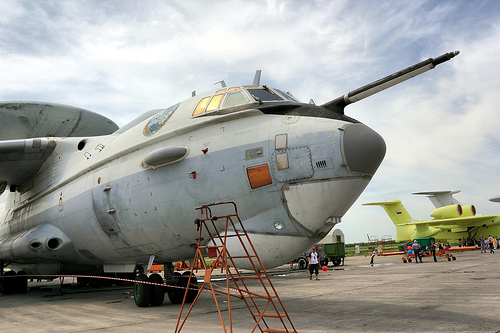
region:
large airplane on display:
[3, 69, 391, 309]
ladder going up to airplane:
[176, 196, 295, 330]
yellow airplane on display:
[379, 198, 491, 230]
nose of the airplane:
[330, 117, 402, 202]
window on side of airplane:
[210, 94, 219, 112]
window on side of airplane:
[198, 102, 205, 120]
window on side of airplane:
[256, 87, 281, 104]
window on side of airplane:
[273, 86, 296, 100]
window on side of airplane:
[150, 105, 180, 133]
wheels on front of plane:
[137, 270, 207, 297]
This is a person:
[411, 232, 425, 264]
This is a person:
[426, 238, 439, 266]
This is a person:
[437, 234, 457, 264]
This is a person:
[370, 242, 378, 267]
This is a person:
[305, 239, 325, 281]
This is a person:
[484, 229, 497, 251]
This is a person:
[478, 232, 488, 251]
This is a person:
[461, 230, 467, 246]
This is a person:
[455, 234, 462, 253]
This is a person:
[468, 235, 478, 249]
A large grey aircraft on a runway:
[14, 32, 406, 327]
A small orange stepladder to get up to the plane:
[184, 203, 286, 331]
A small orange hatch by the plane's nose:
[240, 160, 280, 196]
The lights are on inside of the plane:
[195, 91, 221, 115]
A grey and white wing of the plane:
[0, 135, 77, 200]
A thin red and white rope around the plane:
[0, 251, 190, 296]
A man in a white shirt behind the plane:
[300, 240, 328, 281]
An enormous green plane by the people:
[387, 186, 499, 255]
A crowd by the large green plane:
[451, 232, 498, 257]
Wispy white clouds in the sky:
[122, 20, 281, 88]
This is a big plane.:
[20, 75, 389, 285]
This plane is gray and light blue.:
[78, 135, 347, 246]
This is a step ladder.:
[196, 195, 263, 287]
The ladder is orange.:
[193, 223, 268, 330]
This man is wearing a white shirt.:
[298, 243, 325, 275]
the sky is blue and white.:
[80, 3, 401, 68]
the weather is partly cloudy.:
[56, 13, 354, 75]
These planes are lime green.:
[377, 188, 492, 246]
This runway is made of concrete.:
[319, 285, 472, 327]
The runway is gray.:
[326, 280, 491, 331]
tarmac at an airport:
[350, 275, 491, 325]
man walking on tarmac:
[301, 245, 326, 285]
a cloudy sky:
[402, 91, 492, 168]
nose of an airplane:
[340, 115, 392, 175]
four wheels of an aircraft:
[130, 267, 200, 302]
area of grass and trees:
[346, 237, 391, 249]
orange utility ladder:
[176, 195, 301, 330]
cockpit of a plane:
[190, 80, 305, 120]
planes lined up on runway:
[372, 175, 494, 250]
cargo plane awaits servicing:
[21, 55, 488, 318]